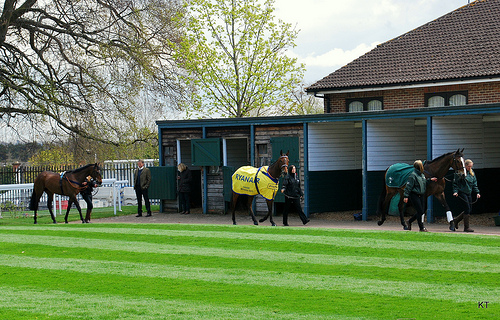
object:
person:
[281, 165, 311, 226]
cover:
[385, 162, 427, 188]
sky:
[0, 0, 468, 143]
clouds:
[314, 53, 358, 70]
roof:
[303, 0, 500, 79]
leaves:
[175, 37, 240, 74]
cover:
[231, 165, 280, 200]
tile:
[457, 52, 469, 55]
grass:
[1, 225, 89, 254]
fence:
[0, 159, 164, 206]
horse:
[377, 148, 467, 232]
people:
[399, 159, 438, 232]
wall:
[325, 126, 342, 163]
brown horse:
[28, 160, 103, 223]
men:
[133, 161, 153, 218]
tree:
[174, 0, 314, 119]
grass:
[0, 223, 500, 320]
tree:
[0, 0, 171, 147]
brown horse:
[232, 149, 290, 226]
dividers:
[426, 117, 494, 224]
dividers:
[362, 118, 427, 222]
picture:
[0, 0, 500, 319]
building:
[155, 0, 500, 217]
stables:
[305, 118, 364, 220]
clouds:
[299, 2, 350, 29]